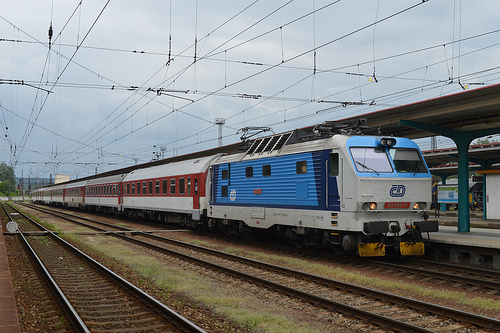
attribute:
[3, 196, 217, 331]
railroad track — silver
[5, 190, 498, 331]
railroad track — silver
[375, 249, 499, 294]
railroad track — silver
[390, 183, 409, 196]
logo — rounded, blue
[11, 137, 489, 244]
train — red and white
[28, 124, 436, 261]
train — blue, gray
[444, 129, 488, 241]
post — green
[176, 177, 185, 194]
window — dark, square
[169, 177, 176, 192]
window — dark, square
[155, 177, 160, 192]
window — dark, square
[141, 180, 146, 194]
window — dark, square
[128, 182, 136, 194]
window — dark, square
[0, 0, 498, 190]
wires — black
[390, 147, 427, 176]
windshield pane — dark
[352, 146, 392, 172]
windshield pane — dark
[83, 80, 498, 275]
train — blue, corrugated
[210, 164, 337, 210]
paint — blue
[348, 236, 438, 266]
mudflaps — black and yellow